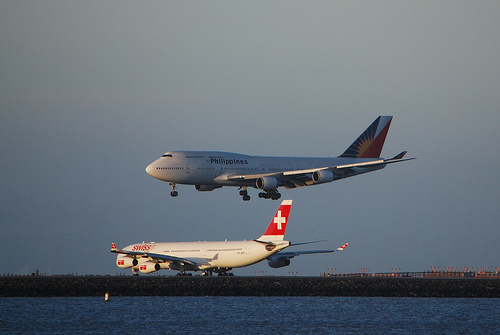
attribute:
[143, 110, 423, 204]
airplane — silver, landing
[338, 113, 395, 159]
tail — colorful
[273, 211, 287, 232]
cross — white on red, white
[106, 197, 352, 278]
plane — white, landing, swiss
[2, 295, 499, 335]
ocean — blue, dark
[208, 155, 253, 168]
philippines — name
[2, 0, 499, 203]
sky — gray, cloudy, dark blue-grey, dark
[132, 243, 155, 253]
swiss — name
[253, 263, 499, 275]
barriers — orange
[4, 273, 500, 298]
coast — rocky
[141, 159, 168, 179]
nose — light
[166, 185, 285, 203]
landing gear — down